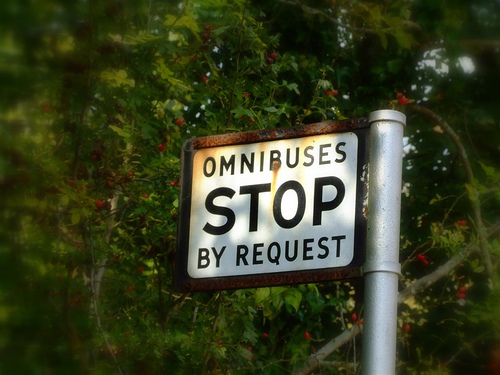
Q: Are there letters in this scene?
A: Yes, there are letters.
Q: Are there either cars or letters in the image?
A: Yes, there are letters.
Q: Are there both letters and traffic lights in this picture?
A: No, there are letters but no traffic lights.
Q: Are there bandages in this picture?
A: No, there are no bandages.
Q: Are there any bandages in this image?
A: No, there are no bandages.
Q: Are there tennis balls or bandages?
A: No, there are no bandages or tennis balls.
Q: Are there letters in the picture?
A: Yes, there are letters.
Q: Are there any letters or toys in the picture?
A: Yes, there are letters.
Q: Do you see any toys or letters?
A: Yes, there are letters.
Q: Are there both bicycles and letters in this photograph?
A: No, there are letters but no bikes.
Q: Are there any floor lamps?
A: No, there are no floor lamps.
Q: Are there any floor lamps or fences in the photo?
A: No, there are no floor lamps or fences.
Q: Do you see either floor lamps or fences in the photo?
A: No, there are no floor lamps or fences.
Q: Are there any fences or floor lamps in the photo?
A: No, there are no floor lamps or fences.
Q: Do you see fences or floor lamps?
A: No, there are no floor lamps or fences.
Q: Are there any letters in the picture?
A: Yes, there are letters.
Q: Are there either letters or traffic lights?
A: Yes, there are letters.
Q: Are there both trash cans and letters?
A: No, there are letters but no trash cans.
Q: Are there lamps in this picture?
A: No, there are no lamps.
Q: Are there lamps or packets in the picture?
A: No, there are no lamps or packets.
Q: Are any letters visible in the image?
A: Yes, there are letters.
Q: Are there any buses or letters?
A: Yes, there are letters.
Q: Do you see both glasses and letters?
A: No, there are letters but no glasses.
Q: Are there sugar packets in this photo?
A: No, there are no sugar packets.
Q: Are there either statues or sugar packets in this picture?
A: No, there are no sugar packets or statues.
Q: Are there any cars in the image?
A: No, there are no cars.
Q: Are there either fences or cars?
A: No, there are no cars or fences.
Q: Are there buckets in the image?
A: No, there are no buckets.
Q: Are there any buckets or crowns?
A: No, there are no buckets or crowns.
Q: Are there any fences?
A: No, there are no fences.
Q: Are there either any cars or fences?
A: No, there are no fences or cars.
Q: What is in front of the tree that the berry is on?
A: The sign is in front of the tree.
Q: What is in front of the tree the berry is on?
A: The sign is in front of the tree.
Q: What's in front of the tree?
A: The sign is in front of the tree.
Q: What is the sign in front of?
A: The sign is in front of the tree.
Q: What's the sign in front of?
A: The sign is in front of the tree.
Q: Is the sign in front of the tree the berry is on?
A: Yes, the sign is in front of the tree.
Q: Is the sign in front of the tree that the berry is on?
A: Yes, the sign is in front of the tree.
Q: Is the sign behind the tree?
A: No, the sign is in front of the tree.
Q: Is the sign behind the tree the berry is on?
A: No, the sign is in front of the tree.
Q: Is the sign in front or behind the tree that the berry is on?
A: The sign is in front of the tree.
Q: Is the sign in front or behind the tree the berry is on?
A: The sign is in front of the tree.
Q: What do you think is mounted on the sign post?
A: The sign is mounted on the sign post.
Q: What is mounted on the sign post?
A: The sign is mounted on the sign post.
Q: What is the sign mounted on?
A: The sign is mounted on the sign post.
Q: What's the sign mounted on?
A: The sign is mounted on the sign post.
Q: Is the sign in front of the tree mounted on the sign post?
A: Yes, the sign is mounted on the sign post.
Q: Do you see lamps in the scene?
A: No, there are no lamps.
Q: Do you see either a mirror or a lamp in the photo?
A: No, there are no lamps or mirrors.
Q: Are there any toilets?
A: No, there are no toilets.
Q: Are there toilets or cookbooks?
A: No, there are no toilets or cookbooks.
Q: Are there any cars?
A: No, there are no cars.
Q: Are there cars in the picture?
A: No, there are no cars.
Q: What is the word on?
A: The word is on the sign.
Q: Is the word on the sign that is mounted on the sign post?
A: Yes, the word is on the sign.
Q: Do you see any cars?
A: No, there are no cars.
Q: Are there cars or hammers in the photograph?
A: No, there are no cars or hammers.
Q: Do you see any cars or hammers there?
A: No, there are no cars or hammers.